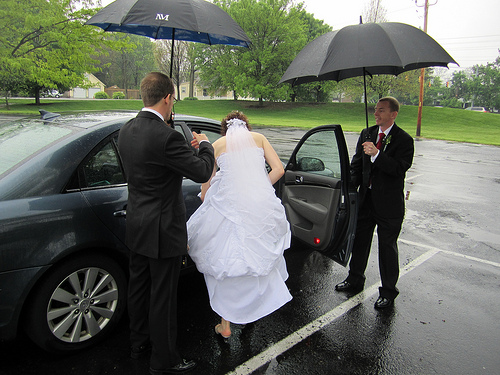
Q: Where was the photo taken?
A: It was taken at the parking lot.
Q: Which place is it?
A: It is a parking lot.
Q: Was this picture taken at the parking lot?
A: Yes, it was taken in the parking lot.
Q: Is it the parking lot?
A: Yes, it is the parking lot.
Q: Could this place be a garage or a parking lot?
A: It is a parking lot.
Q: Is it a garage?
A: No, it is a parking lot.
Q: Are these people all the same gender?
A: No, they are both male and female.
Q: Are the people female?
A: No, they are both male and female.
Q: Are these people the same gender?
A: No, they are both male and female.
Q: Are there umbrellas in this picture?
A: Yes, there is an umbrella.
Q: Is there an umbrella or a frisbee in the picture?
A: Yes, there is an umbrella.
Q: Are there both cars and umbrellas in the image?
A: Yes, there are both an umbrella and a car.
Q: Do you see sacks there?
A: No, there are no sacks.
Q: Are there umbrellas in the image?
A: Yes, there is an umbrella.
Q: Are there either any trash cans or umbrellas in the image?
A: Yes, there is an umbrella.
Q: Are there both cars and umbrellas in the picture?
A: Yes, there are both an umbrella and a car.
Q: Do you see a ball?
A: No, there are no balls.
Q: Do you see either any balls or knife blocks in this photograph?
A: No, there are no balls or knife blocks.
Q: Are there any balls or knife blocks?
A: No, there are no balls or knife blocks.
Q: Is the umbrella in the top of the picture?
A: Yes, the umbrella is in the top of the image.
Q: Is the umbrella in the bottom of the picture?
A: No, the umbrella is in the top of the image.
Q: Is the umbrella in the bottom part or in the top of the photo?
A: The umbrella is in the top of the image.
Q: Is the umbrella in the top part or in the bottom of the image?
A: The umbrella is in the top of the image.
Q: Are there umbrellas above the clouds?
A: Yes, there is an umbrella above the clouds.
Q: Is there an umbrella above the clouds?
A: Yes, there is an umbrella above the clouds.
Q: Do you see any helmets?
A: No, there are no helmets.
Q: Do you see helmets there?
A: No, there are no helmets.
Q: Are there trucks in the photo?
A: No, there are no trucks.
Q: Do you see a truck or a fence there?
A: No, there are no trucks or fences.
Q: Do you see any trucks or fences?
A: No, there are no trucks or fences.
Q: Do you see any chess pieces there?
A: No, there are no chess pieces.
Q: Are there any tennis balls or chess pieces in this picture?
A: No, there are no chess pieces or tennis balls.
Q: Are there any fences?
A: No, there are no fences.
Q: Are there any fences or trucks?
A: No, there are no fences or trucks.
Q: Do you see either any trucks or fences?
A: No, there are no fences or trucks.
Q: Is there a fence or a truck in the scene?
A: No, there are no fences or trucks.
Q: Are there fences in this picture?
A: No, there are no fences.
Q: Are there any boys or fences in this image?
A: No, there are no fences or boys.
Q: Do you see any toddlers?
A: No, there are no toddlers.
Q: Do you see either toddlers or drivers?
A: No, there are no toddlers or drivers.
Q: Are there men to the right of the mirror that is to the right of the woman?
A: Yes, there is a man to the right of the mirror.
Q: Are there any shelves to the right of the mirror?
A: No, there is a man to the right of the mirror.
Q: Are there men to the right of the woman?
A: Yes, there is a man to the right of the woman.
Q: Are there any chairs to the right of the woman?
A: No, there is a man to the right of the woman.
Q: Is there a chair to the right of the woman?
A: No, there is a man to the right of the woman.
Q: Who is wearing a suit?
A: The man is wearing a suit.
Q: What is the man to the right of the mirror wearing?
A: The man is wearing a suit.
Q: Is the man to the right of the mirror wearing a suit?
A: Yes, the man is wearing a suit.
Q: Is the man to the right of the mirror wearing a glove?
A: No, the man is wearing a suit.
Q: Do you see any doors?
A: Yes, there is a door.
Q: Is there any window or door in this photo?
A: Yes, there is a door.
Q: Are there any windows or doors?
A: Yes, there is a door.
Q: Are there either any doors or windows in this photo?
A: Yes, there is a door.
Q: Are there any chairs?
A: No, there are no chairs.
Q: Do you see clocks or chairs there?
A: No, there are no chairs or clocks.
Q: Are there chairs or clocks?
A: No, there are no chairs or clocks.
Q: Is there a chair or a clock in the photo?
A: No, there are no chairs or clocks.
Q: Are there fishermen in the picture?
A: No, there are no fishermen.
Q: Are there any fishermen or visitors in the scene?
A: No, there are no fishermen or visitors.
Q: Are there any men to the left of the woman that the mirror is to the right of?
A: Yes, there is a man to the left of the woman.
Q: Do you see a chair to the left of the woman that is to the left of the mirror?
A: No, there is a man to the left of the woman.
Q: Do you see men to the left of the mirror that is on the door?
A: Yes, there is a man to the left of the mirror.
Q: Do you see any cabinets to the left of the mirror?
A: No, there is a man to the left of the mirror.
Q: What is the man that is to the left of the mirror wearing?
A: The man is wearing a suit.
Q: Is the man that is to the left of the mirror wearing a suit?
A: Yes, the man is wearing a suit.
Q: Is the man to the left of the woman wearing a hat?
A: No, the man is wearing a suit.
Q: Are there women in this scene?
A: Yes, there is a woman.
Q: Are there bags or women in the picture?
A: Yes, there is a woman.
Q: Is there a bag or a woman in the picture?
A: Yes, there is a woman.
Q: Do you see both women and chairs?
A: No, there is a woman but no chairs.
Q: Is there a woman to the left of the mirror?
A: Yes, there is a woman to the left of the mirror.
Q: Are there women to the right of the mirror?
A: No, the woman is to the left of the mirror.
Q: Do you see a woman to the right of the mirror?
A: No, the woman is to the left of the mirror.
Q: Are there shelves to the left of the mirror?
A: No, there is a woman to the left of the mirror.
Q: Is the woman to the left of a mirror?
A: Yes, the woman is to the left of a mirror.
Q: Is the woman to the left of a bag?
A: No, the woman is to the left of a mirror.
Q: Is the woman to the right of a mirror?
A: No, the woman is to the left of a mirror.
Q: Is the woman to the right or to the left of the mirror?
A: The woman is to the left of the mirror.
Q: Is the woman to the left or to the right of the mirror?
A: The woman is to the left of the mirror.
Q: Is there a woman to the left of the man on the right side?
A: Yes, there is a woman to the left of the man.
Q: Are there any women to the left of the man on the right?
A: Yes, there is a woman to the left of the man.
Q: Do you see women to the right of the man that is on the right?
A: No, the woman is to the left of the man.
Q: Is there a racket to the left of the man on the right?
A: No, there is a woman to the left of the man.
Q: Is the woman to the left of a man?
A: Yes, the woman is to the left of a man.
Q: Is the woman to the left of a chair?
A: No, the woman is to the left of a man.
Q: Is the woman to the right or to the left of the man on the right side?
A: The woman is to the left of the man.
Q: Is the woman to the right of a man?
A: Yes, the woman is to the right of a man.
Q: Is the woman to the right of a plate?
A: No, the woman is to the right of a man.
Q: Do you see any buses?
A: No, there are no buses.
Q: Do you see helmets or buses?
A: No, there are no buses or helmets.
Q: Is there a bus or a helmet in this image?
A: No, there are no buses or helmets.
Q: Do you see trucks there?
A: No, there are no trucks.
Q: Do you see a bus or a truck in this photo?
A: No, there are no trucks or buses.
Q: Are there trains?
A: No, there are no trains.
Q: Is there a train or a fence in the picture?
A: No, there are no trains or fences.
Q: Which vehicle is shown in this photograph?
A: The vehicle is a car.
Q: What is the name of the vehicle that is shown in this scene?
A: The vehicle is a car.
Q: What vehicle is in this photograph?
A: The vehicle is a car.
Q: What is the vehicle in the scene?
A: The vehicle is a car.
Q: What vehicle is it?
A: The vehicle is a car.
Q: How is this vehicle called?
A: That is a car.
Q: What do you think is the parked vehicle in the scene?
A: The vehicle is a car.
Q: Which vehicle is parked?
A: The vehicle is a car.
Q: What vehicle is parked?
A: The vehicle is a car.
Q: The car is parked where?
A: The car is parked in the parking lot.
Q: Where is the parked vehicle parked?
A: The car is parked in the parking lot.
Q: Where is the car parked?
A: The car is parked in the parking lot.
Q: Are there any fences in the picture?
A: No, there are no fences.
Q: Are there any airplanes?
A: No, there are no airplanes.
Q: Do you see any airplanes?
A: No, there are no airplanes.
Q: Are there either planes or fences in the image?
A: No, there are no planes or fences.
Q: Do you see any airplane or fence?
A: No, there are no airplanes or fences.